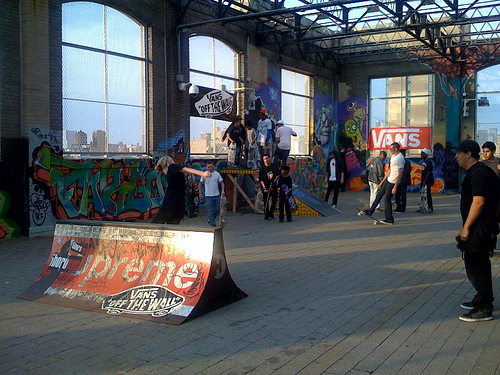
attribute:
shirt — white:
[201, 171, 224, 198]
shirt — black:
[458, 162, 499, 248]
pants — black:
[462, 242, 494, 311]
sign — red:
[365, 126, 434, 150]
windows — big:
[60, 2, 148, 155]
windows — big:
[190, 37, 241, 158]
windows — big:
[370, 74, 437, 127]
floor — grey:
[2, 187, 500, 374]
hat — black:
[450, 140, 483, 161]